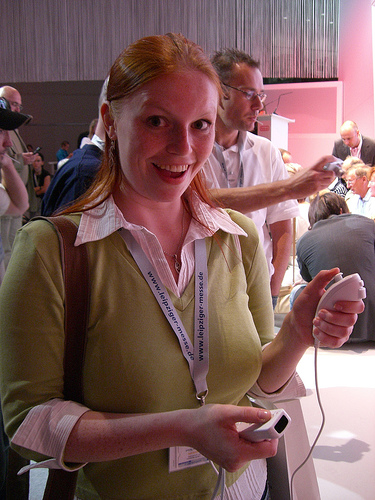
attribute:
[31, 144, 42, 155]
cellphone — black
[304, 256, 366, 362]
controller — white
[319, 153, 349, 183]
camera — digital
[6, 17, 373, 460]
woman — hand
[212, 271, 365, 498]
wii nunchuck — white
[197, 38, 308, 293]
man — mouth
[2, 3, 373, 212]
wall — pink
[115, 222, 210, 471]
lanyard — black and white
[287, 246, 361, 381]
game controller — wii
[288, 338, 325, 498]
cord — white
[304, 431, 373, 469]
shadow — ground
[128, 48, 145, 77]
hair — red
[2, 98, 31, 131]
cap — black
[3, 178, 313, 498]
shirt — black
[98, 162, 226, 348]
neck — womans